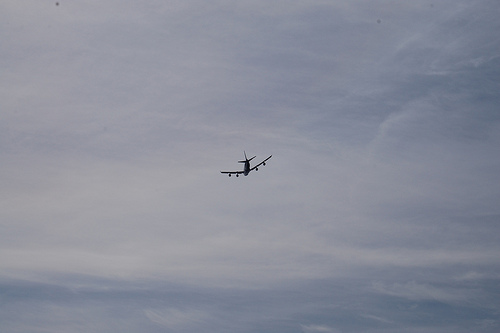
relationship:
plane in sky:
[218, 150, 274, 180] [0, 1, 499, 331]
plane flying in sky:
[218, 150, 274, 180] [0, 1, 499, 331]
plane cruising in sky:
[218, 150, 274, 180] [0, 1, 499, 331]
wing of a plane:
[252, 152, 272, 170] [218, 150, 274, 180]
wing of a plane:
[221, 166, 243, 177] [218, 150, 274, 180]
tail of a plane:
[239, 149, 256, 164] [218, 150, 274, 180]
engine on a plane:
[262, 162, 268, 167] [218, 150, 274, 180]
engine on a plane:
[254, 165, 259, 174] [218, 150, 274, 180]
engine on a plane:
[236, 172, 240, 181] [218, 150, 274, 180]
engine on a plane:
[228, 174, 233, 178] [218, 150, 274, 180]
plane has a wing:
[218, 150, 274, 180] [252, 152, 272, 170]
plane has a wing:
[218, 150, 274, 180] [221, 166, 243, 177]